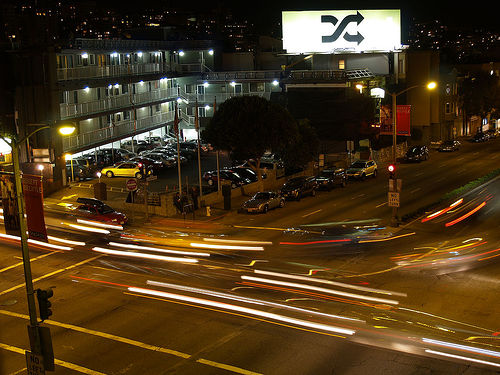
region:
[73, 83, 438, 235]
cars parked inside and outside of lot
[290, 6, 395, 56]
lit sign with two black arrows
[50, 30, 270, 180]
outside lighting on every floor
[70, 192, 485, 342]
bright lights whizzing by on street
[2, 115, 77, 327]
lamppost with traffic light and banner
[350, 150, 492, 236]
thin island in middle of street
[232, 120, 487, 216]
cars parked along a curb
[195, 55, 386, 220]
bushy trees above low wall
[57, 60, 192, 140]
railings across building floors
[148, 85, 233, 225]
tall white poles with flags on top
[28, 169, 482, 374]
Appearance traffic camera neon fast.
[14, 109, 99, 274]
Street light high above traffic.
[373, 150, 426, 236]
No u-turn sign traffic light.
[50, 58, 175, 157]
Motel lights on balcony doors.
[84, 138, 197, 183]
Well lit motel parking lot.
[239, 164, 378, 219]
Vehicles line wait traffic light.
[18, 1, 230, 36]
Dim city lights background.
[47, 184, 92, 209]
Parking lot white arrow direction.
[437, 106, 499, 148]
Storefront buildings along street.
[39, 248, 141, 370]
Yellow lined pedestrian crosswalks.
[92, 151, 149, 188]
Car parked in parking lot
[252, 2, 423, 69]
Large white sign with black symbol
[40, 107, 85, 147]
Lit street lamp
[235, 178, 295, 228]
Car parked on side of street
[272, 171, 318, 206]
Car parked on side of street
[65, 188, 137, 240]
Car parked on side of street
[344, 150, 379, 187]
Car parked on side of street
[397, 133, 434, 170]
Car parked on side of street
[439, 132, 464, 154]
Car parked on side of street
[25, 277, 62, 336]
Black metal traffic light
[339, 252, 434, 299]
part of the road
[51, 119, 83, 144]
part of a street light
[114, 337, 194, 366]
white lines on the road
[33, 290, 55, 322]
part of a traffic light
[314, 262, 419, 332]
fast lights of cars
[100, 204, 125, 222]
part of a red car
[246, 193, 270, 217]
part of a grey car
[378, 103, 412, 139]
part of a red banner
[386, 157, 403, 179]
part of a red light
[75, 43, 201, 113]
lights in a building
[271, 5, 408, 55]
a billboard with an obscure message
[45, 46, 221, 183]
a group of apartments or hotel rooms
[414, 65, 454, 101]
a lonely light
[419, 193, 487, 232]
time lapse of tail lights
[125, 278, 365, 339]
time lapse of headlights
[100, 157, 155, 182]
a car parked in the light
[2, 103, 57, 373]
a pole holding a signal light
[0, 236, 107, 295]
cross walk in an intersection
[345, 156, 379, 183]
an SUV parked on the street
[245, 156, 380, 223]
a row of parked cars